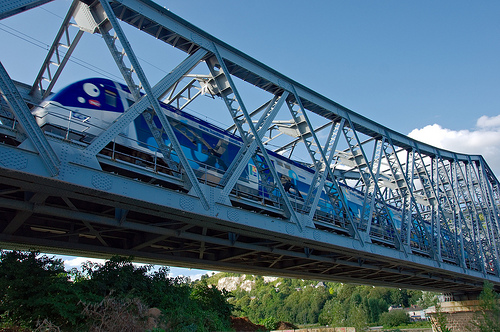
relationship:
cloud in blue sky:
[332, 116, 499, 210] [0, 3, 499, 142]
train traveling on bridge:
[30, 75, 485, 268] [2, 1, 499, 295]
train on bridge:
[30, 75, 485, 268] [2, 1, 499, 295]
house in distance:
[406, 305, 432, 321] [345, 273, 498, 324]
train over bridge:
[30, 75, 485, 268] [48, 40, 468, 273]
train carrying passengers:
[30, 75, 485, 268] [158, 117, 227, 145]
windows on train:
[170, 111, 319, 174] [44, 69, 490, 291]